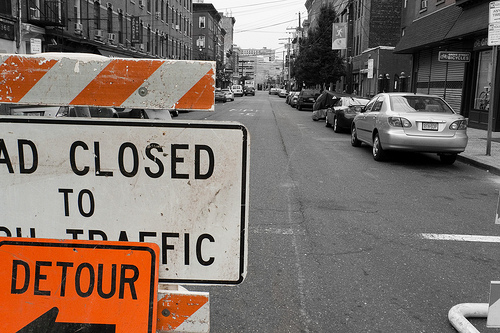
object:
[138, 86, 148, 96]
bolt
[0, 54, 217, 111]
traffic barrier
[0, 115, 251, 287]
sign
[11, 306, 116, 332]
arrow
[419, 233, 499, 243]
line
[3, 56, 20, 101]
specks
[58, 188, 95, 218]
word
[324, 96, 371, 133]
cars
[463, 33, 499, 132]
shops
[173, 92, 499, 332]
street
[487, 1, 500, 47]
sign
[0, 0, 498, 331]
city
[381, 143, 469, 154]
bumper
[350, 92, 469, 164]
car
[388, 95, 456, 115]
window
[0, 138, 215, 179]
lettering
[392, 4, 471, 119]
facade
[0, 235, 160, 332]
sign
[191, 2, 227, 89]
buildings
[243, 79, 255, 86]
bus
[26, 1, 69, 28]
balcony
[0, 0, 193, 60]
building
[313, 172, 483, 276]
ground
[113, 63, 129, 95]
orange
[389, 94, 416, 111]
light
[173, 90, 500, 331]
road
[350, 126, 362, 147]
tire